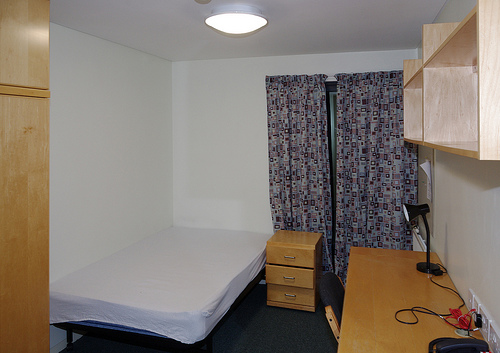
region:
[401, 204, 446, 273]
black lamp on desk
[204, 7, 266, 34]
round white light on ceiling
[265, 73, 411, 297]
curtains covering a window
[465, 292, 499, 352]
three electrical outlets on wall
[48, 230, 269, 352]
bed covered with white sheet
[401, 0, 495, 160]
wooden shelving on wall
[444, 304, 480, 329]
red cord sitting on desk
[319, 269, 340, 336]
black desk chair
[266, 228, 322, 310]
set of drawers beside bed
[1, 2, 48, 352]
wooden cabinet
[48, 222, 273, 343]
a mattress with a white sheet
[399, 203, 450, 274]
a black table lamp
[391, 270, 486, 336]
a black cord and plug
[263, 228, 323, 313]
a bed side table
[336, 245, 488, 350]
a desk against the wall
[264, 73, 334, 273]
a long window curtain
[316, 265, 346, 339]
a chair at the desk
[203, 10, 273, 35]
a round ceiling light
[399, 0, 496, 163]
shelves attached to the wall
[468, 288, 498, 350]
outlets in the wall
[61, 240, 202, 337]
the bed sheet is white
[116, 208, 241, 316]
the bed sheet is white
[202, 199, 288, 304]
the bed sheet is white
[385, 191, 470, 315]
a black lamp on table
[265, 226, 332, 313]
a small brown drawer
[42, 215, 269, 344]
a white twin bed sheet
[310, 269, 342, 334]
part of a desk chair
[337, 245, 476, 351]
a long brown table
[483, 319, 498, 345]
a white electrical outlet plate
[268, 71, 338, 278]
long window curtains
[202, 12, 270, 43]
a ceiling light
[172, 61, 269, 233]
a long white wall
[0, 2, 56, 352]
a long brown cabinet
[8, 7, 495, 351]
A small bedroom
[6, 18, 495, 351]
An empty dorm room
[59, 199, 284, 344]
A bed without sheets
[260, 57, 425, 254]
Curtains on the window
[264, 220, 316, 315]
Three drawers in a stand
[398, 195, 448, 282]
A lamp on a desk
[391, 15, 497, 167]
A shelf above a desk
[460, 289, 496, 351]
Plug in outlets on the wall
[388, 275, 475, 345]
A cord on the desk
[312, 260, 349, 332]
A chair at a desk